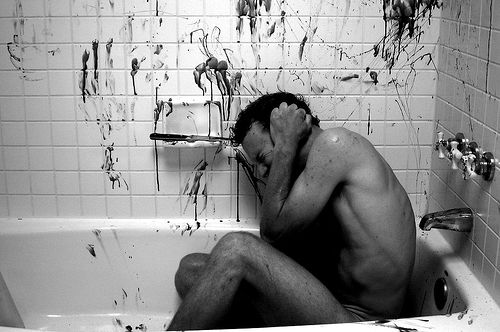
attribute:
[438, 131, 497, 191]
faucet — cold water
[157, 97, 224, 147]
dish — soap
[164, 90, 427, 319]
man — distraught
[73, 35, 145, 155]
prints — bloody, hand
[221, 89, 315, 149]
hair — dark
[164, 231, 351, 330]
legs — hairy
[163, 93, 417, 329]
guy — naked